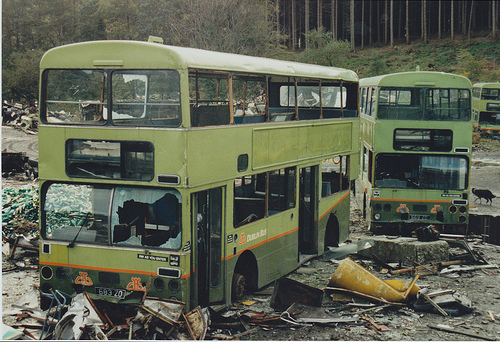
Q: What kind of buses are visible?
A: Double-decker.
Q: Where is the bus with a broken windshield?
A: On the left.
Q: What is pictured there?
A: Bus.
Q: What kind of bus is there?
A: Double decker.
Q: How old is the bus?
A: Very old.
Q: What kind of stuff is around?
A: Garbage.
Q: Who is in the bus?
A: No person.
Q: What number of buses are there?
A: 2.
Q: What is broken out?
A: Windows.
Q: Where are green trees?
A: Along the back.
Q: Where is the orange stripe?
A: On the bus.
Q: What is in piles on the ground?
A: Metal.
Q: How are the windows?
A: Broken.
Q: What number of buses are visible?
A: Three.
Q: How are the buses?
A: Broken.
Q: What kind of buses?
A: Double decker.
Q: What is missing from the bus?
A: Wheels.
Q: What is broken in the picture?
A: Buses.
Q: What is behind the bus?
A: Another bus.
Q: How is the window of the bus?
A: Broken.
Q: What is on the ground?
A: Trash.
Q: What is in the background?
A: Trees.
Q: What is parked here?
A: Two buses.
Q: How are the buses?
A: Old and broken.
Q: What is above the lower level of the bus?
A: Another level.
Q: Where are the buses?
A: In a junkyard.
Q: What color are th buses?
A: Green.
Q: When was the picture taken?
A: During the day.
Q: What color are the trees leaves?
A: Green.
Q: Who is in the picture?
A: There are no people in the image.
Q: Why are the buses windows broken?
A: They are in a junk yard.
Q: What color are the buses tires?
A: The buses do not have tires.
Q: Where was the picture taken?
A: Auto junk yard.